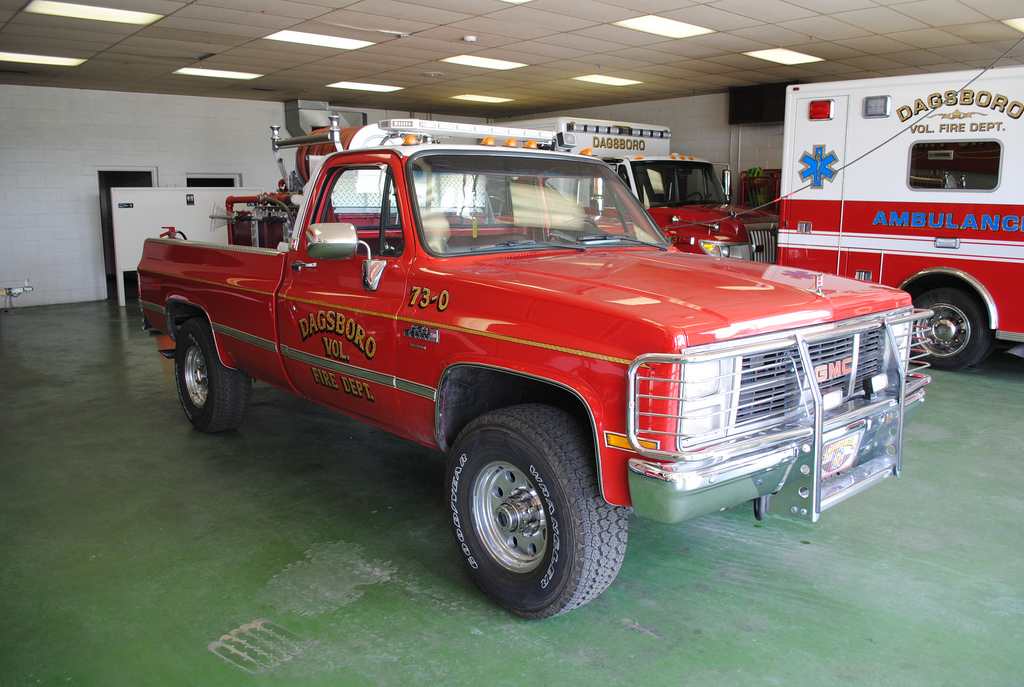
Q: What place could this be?
A: It is a garage.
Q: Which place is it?
A: It is a garage.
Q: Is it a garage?
A: Yes, it is a garage.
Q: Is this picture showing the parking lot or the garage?
A: It is showing the garage.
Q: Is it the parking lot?
A: No, it is the garage.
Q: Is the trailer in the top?
A: Yes, the trailer is in the top of the image.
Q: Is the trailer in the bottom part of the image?
A: No, the trailer is in the top of the image.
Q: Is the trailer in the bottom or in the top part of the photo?
A: The trailer is in the top of the image.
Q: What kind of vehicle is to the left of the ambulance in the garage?
A: The vehicle is a trailer.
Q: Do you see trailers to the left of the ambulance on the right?
A: Yes, there is a trailer to the left of the ambulance.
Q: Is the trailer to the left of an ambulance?
A: Yes, the trailer is to the left of an ambulance.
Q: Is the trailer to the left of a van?
A: No, the trailer is to the left of an ambulance.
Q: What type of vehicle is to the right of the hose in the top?
A: The vehicle is a trailer.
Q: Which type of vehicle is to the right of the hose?
A: The vehicle is a trailer.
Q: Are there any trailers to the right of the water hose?
A: Yes, there is a trailer to the right of the water hose.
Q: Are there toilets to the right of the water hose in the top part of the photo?
A: No, there is a trailer to the right of the water hose.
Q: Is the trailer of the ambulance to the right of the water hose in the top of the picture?
A: Yes, the trailer is to the right of the water hose.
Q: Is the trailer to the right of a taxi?
A: No, the trailer is to the right of the water hose.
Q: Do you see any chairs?
A: No, there are no chairs.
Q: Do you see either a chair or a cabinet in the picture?
A: No, there are no chairs or cabinets.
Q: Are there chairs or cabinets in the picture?
A: No, there are no chairs or cabinets.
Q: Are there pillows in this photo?
A: No, there are no pillows.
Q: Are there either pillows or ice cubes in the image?
A: No, there are no pillows or ice cubes.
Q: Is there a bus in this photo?
A: No, there are no buses.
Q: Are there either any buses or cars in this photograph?
A: No, there are no buses or cars.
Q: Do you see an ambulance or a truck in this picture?
A: Yes, there is an ambulance.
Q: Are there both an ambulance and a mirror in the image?
A: Yes, there are both an ambulance and a mirror.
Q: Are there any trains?
A: No, there are no trains.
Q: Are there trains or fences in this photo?
A: No, there are no trains or fences.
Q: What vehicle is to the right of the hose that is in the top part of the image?
A: The vehicle is an ambulance.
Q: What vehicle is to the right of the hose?
A: The vehicle is an ambulance.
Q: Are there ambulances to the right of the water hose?
A: Yes, there is an ambulance to the right of the water hose.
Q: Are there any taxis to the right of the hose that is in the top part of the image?
A: No, there is an ambulance to the right of the hose.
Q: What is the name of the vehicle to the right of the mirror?
A: The vehicle is an ambulance.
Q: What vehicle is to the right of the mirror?
A: The vehicle is an ambulance.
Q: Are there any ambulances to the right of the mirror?
A: Yes, there is an ambulance to the right of the mirror.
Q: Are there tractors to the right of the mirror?
A: No, there is an ambulance to the right of the mirror.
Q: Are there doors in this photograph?
A: Yes, there is a door.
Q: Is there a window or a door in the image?
A: Yes, there is a door.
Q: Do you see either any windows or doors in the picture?
A: Yes, there is a door.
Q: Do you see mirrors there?
A: Yes, there is a mirror.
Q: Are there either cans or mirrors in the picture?
A: Yes, there is a mirror.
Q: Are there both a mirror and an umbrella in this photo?
A: No, there is a mirror but no umbrellas.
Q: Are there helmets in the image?
A: No, there are no helmets.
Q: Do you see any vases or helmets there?
A: No, there are no helmets or vases.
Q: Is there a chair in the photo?
A: No, there are no chairs.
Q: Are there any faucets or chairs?
A: No, there are no chairs or faucets.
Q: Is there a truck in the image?
A: Yes, there is a truck.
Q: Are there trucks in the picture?
A: Yes, there is a truck.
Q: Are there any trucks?
A: Yes, there is a truck.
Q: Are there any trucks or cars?
A: Yes, there is a truck.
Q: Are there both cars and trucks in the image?
A: No, there is a truck but no cars.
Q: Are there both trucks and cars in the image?
A: No, there is a truck but no cars.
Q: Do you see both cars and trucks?
A: No, there is a truck but no cars.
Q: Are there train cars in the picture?
A: No, there are no train cars.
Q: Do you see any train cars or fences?
A: No, there are no train cars or fences.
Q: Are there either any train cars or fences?
A: No, there are no train cars or fences.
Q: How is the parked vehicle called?
A: The vehicle is a truck.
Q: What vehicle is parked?
A: The vehicle is a truck.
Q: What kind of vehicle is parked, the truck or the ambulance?
A: The truck is parked.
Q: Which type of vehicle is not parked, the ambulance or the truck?
A: The ambulance is not parked.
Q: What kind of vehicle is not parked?
A: The vehicle is an ambulance.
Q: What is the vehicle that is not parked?
A: The vehicle is an ambulance.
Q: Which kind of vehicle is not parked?
A: The vehicle is an ambulance.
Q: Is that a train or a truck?
A: That is a truck.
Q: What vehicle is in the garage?
A: The vehicle is a truck.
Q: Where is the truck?
A: The truck is in the garage.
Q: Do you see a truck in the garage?
A: Yes, there is a truck in the garage.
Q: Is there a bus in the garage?
A: No, there is a truck in the garage.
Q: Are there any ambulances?
A: Yes, there is an ambulance.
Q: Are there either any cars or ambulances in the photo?
A: Yes, there is an ambulance.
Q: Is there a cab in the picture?
A: No, there are no taxis.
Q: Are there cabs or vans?
A: No, there are no cabs or vans.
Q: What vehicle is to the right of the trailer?
A: The vehicle is an ambulance.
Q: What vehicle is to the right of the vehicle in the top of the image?
A: The vehicle is an ambulance.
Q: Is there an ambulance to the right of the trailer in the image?
A: Yes, there is an ambulance to the right of the trailer.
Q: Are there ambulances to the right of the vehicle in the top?
A: Yes, there is an ambulance to the right of the trailer.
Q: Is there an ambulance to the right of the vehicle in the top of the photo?
A: Yes, there is an ambulance to the right of the trailer.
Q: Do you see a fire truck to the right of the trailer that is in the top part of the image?
A: No, there is an ambulance to the right of the trailer.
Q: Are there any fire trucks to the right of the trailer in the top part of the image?
A: No, there is an ambulance to the right of the trailer.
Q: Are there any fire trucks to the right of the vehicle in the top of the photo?
A: No, there is an ambulance to the right of the trailer.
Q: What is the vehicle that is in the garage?
A: The vehicle is an ambulance.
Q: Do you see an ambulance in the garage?
A: Yes, there is an ambulance in the garage.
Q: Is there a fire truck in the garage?
A: No, there is an ambulance in the garage.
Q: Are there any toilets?
A: No, there are no toilets.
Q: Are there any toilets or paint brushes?
A: No, there are no toilets or paint brushes.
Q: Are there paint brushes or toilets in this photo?
A: No, there are no toilets or paint brushes.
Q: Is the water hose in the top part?
A: Yes, the water hose is in the top of the image.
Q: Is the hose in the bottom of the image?
A: No, the hose is in the top of the image.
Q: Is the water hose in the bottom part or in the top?
A: The water hose is in the top of the image.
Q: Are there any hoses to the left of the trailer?
A: Yes, there is a hose to the left of the trailer.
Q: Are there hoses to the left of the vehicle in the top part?
A: Yes, there is a hose to the left of the trailer.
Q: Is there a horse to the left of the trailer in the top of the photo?
A: No, there is a hose to the left of the trailer.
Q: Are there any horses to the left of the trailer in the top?
A: No, there is a hose to the left of the trailer.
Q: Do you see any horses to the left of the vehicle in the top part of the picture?
A: No, there is a hose to the left of the trailer.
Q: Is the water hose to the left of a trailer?
A: Yes, the water hose is to the left of a trailer.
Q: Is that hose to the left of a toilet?
A: No, the hose is to the left of a trailer.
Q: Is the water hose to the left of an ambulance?
A: Yes, the water hose is to the left of an ambulance.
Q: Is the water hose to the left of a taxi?
A: No, the water hose is to the left of an ambulance.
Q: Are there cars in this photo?
A: No, there are no cars.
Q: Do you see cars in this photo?
A: No, there are no cars.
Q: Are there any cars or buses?
A: No, there are no cars or buses.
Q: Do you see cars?
A: No, there are no cars.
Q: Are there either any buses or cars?
A: No, there are no cars or buses.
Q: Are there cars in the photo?
A: No, there are no cars.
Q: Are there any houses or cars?
A: No, there are no cars or houses.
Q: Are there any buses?
A: No, there are no buses.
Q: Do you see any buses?
A: No, there are no buses.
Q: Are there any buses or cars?
A: No, there are no buses or cars.